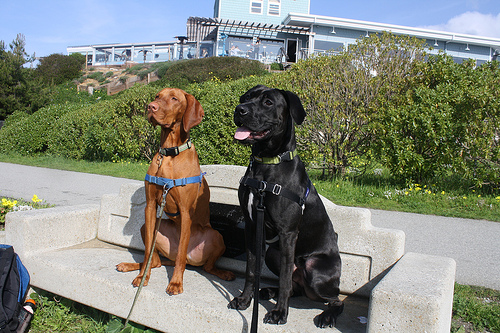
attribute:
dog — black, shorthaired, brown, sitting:
[113, 53, 234, 311]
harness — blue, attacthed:
[124, 178, 223, 198]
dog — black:
[224, 78, 342, 327]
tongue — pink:
[231, 120, 246, 144]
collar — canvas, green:
[142, 138, 206, 174]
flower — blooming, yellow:
[0, 191, 55, 214]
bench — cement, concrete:
[36, 146, 431, 332]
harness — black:
[233, 169, 334, 219]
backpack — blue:
[7, 241, 51, 333]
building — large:
[91, 15, 499, 70]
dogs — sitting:
[99, 84, 366, 323]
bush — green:
[375, 62, 495, 183]